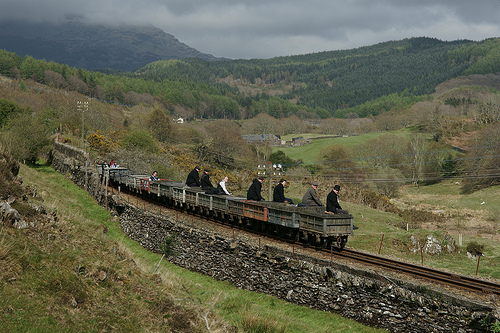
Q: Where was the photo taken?
A: It was taken at the field.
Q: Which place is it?
A: It is a field.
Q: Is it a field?
A: Yes, it is a field.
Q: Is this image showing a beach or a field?
A: It is showing a field.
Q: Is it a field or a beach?
A: It is a field.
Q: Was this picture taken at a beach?
A: No, the picture was taken in a field.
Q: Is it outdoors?
A: Yes, it is outdoors.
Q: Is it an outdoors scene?
A: Yes, it is outdoors.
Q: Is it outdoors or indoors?
A: It is outdoors.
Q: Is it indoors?
A: No, it is outdoors.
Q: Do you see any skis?
A: No, there are no skis.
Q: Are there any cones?
A: No, there are no cones.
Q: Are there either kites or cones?
A: No, there are no cones or kites.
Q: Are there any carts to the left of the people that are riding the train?
A: Yes, there is a cart to the left of the men.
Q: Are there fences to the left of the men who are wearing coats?
A: No, there is a cart to the left of the men.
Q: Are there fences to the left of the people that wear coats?
A: No, there is a cart to the left of the men.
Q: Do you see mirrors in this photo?
A: No, there are no mirrors.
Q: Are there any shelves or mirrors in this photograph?
A: No, there are no mirrors or shelves.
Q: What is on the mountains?
A: The trees are on the mountains.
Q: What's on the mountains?
A: The trees are on the mountains.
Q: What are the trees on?
A: The trees are on the mountains.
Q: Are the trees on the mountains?
A: Yes, the trees are on the mountains.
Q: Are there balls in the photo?
A: No, there are no balls.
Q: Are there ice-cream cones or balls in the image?
A: No, there are no balls or ice-cream cones.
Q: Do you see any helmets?
A: No, there are no helmets.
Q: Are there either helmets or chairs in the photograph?
A: No, there are no helmets or chairs.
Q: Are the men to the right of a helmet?
A: No, the men are to the right of a person.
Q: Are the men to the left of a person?
A: No, the men are to the right of a person.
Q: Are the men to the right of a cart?
A: Yes, the men are to the right of a cart.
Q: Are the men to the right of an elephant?
A: No, the men are to the right of a cart.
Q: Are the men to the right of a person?
A: Yes, the men are to the right of a person.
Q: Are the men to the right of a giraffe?
A: No, the men are to the right of a person.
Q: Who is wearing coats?
A: The men are wearing coats.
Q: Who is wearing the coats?
A: The men are wearing coats.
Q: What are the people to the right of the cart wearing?
A: The men are wearing coats.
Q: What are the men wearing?
A: The men are wearing coats.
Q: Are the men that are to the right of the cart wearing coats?
A: Yes, the men are wearing coats.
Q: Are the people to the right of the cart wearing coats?
A: Yes, the men are wearing coats.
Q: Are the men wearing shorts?
A: No, the men are wearing coats.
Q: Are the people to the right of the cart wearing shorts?
A: No, the men are wearing coats.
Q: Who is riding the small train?
A: The men are riding the train.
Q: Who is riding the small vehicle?
A: The men are riding the train.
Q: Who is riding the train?
A: The men are riding the train.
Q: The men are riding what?
A: The men are riding the train.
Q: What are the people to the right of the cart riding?
A: The men are riding the train.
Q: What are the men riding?
A: The men are riding the train.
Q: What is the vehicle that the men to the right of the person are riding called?
A: The vehicle is a train.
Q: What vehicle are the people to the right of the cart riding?
A: The men are riding the train.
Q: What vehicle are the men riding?
A: The men are riding the train.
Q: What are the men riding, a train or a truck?
A: The men are riding a train.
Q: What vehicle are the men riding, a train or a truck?
A: The men are riding a train.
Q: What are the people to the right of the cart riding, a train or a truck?
A: The men are riding a train.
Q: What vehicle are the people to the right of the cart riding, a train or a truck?
A: The men are riding a train.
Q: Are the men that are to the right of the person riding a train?
A: Yes, the men are riding a train.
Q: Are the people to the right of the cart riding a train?
A: Yes, the men are riding a train.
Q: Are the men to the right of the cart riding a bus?
A: No, the men are riding a train.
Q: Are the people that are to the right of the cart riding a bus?
A: No, the men are riding a train.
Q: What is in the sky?
A: The clouds are in the sky.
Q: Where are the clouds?
A: The clouds are in the sky.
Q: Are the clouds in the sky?
A: Yes, the clouds are in the sky.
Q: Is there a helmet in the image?
A: No, there are no helmets.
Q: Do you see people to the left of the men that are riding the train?
A: Yes, there is a person to the left of the men.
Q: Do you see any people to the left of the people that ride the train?
A: Yes, there is a person to the left of the men.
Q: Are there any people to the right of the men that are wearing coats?
A: No, the person is to the left of the men.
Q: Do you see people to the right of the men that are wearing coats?
A: No, the person is to the left of the men.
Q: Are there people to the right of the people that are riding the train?
A: No, the person is to the left of the men.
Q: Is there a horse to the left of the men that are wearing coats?
A: No, there is a person to the left of the men.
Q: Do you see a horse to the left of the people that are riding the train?
A: No, there is a person to the left of the men.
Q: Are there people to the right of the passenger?
A: Yes, there is a person to the right of the passenger.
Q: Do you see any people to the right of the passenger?
A: Yes, there is a person to the right of the passenger.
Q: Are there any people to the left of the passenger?
A: No, the person is to the right of the passenger.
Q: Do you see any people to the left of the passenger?
A: No, the person is to the right of the passenger.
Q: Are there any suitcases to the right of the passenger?
A: No, there is a person to the right of the passenger.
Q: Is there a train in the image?
A: Yes, there is a train.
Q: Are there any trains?
A: Yes, there is a train.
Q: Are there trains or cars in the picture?
A: Yes, there is a train.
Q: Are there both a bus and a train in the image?
A: No, there is a train but no buses.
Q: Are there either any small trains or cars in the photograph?
A: Yes, there is a small train.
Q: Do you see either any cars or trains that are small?
A: Yes, the train is small.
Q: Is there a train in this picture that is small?
A: Yes, there is a small train.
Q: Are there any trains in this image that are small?
A: Yes, there is a train that is small.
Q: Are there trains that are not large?
A: Yes, there is a small train.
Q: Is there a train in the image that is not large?
A: Yes, there is a small train.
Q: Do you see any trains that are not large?
A: Yes, there is a small train.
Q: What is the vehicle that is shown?
A: The vehicle is a train.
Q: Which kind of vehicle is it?
A: The vehicle is a train.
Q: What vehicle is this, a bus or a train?
A: This is a train.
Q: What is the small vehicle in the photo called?
A: The vehicle is a train.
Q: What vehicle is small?
A: The vehicle is a train.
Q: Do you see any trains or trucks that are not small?
A: No, there is a train but it is small.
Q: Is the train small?
A: Yes, the train is small.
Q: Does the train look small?
A: Yes, the train is small.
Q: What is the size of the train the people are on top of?
A: The train is small.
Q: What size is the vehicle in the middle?
A: The train is small.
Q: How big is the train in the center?
A: The train is small.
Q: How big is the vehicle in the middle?
A: The train is small.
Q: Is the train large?
A: No, the train is small.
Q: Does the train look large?
A: No, the train is small.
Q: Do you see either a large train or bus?
A: No, there is a train but it is small.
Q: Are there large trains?
A: No, there is a train but it is small.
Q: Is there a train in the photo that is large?
A: No, there is a train but it is small.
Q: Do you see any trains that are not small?
A: No, there is a train but it is small.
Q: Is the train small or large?
A: The train is small.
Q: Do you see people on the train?
A: Yes, there are people on the train.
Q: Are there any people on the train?
A: Yes, there are people on the train.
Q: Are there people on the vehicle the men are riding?
A: Yes, there are people on the train.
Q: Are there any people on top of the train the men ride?
A: Yes, there are people on top of the train.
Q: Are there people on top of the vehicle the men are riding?
A: Yes, there are people on top of the train.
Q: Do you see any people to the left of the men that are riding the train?
A: Yes, there is a person to the left of the men.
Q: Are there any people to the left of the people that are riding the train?
A: Yes, there is a person to the left of the men.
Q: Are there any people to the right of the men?
A: No, the person is to the left of the men.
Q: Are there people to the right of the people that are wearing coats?
A: No, the person is to the left of the men.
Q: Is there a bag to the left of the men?
A: No, there is a person to the left of the men.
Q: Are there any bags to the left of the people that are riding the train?
A: No, there is a person to the left of the men.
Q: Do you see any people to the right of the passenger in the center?
A: Yes, there is a person to the right of the passenger.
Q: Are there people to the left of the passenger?
A: No, the person is to the right of the passenger.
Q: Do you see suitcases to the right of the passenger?
A: No, there is a person to the right of the passenger.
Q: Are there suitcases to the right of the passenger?
A: No, there is a person to the right of the passenger.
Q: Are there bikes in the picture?
A: No, there are no bikes.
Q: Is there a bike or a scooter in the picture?
A: No, there are no bikes or scooters.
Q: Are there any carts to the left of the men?
A: Yes, there is a cart to the left of the men.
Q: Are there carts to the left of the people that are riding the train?
A: Yes, there is a cart to the left of the men.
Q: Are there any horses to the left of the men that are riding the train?
A: No, there is a cart to the left of the men.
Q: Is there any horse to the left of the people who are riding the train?
A: No, there is a cart to the left of the men.